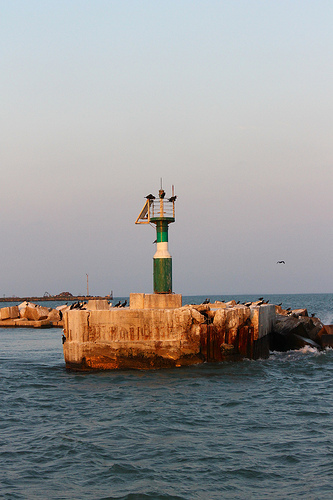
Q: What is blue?
A: Sky.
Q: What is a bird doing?
A: Flying.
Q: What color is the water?
A: Blue.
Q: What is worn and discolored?
A: Rocks.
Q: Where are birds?
A: Sitting on the rock.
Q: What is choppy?
A: The water.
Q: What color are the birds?
A: Black.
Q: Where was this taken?
A: Ocean.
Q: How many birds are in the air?
A: 1.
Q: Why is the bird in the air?
A: Flying.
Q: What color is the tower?
A: Green and white.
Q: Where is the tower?
A: On top of the rock.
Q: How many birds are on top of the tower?
A: 3.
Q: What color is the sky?
A: Blue.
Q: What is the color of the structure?
A: Green and white.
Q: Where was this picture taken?
A: Ocean.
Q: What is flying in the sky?
A: An airplane.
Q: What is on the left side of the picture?
A: An island.